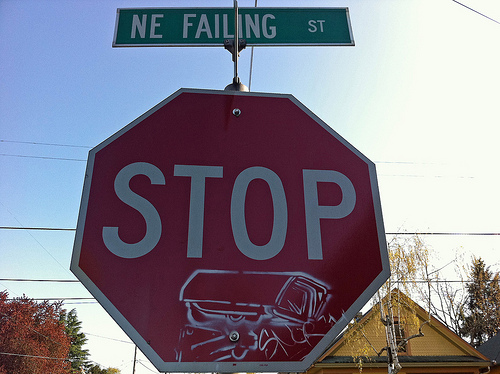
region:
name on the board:
[111, 4, 394, 66]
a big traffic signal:
[108, 102, 416, 363]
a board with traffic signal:
[64, 74, 449, 371]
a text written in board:
[111, 141, 366, 321]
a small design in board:
[183, 259, 357, 367]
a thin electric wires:
[16, 200, 491, 295]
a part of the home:
[333, 284, 487, 371]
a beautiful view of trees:
[4, 282, 101, 369]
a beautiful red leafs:
[1, 301, 101, 371]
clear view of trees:
[389, 246, 498, 361]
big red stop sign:
[52, 78, 407, 369]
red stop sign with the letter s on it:
[60, 137, 400, 287]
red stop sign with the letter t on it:
[53, 128, 414, 285]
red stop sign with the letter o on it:
[57, 158, 397, 306]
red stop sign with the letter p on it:
[86, 159, 391, 290]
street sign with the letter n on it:
[89, 9, 369, 81]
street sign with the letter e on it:
[78, 7, 370, 60]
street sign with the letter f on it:
[98, 10, 364, 49]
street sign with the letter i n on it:
[62, 10, 369, 76]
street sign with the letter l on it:
[69, 5, 366, 61]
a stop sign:
[112, 100, 224, 305]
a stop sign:
[178, 202, 283, 354]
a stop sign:
[191, 197, 248, 277]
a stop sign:
[204, 247, 272, 348]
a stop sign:
[221, 204, 298, 361]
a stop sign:
[208, 217, 276, 317]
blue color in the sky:
[50, 63, 107, 110]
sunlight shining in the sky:
[353, 83, 450, 137]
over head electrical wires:
[8, 207, 67, 267]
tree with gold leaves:
[15, 315, 57, 371]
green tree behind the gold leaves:
[43, 307, 95, 353]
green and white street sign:
[111, 7, 345, 68]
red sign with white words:
[55, 74, 416, 349]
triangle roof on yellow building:
[379, 283, 491, 355]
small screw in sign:
[218, 99, 272, 129]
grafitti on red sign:
[185, 251, 338, 333]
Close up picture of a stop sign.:
[21, 2, 466, 364]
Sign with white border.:
[67, 81, 407, 372]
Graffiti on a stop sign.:
[92, 140, 343, 371]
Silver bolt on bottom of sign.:
[223, 320, 248, 345]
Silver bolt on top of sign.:
[228, 98, 249, 121]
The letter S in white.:
[101, 150, 178, 266]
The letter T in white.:
[168, 157, 228, 261]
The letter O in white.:
[226, 157, 294, 273]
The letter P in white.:
[298, 155, 352, 277]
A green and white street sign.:
[103, 1, 369, 63]